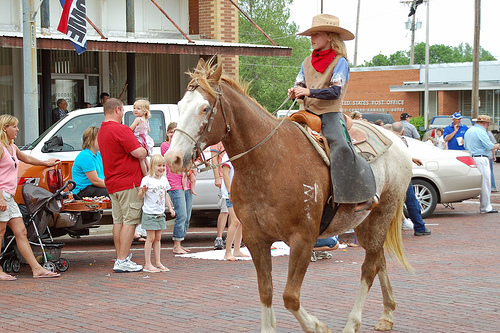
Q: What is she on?
A: Horse.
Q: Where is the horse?
A: On the street.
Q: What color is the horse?
A: Brown.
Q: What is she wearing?
A: Hat.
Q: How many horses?
A: 1.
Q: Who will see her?
A: People.